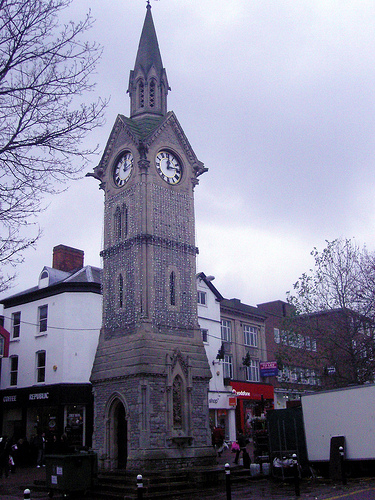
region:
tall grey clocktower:
[77, 10, 248, 468]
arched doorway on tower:
[63, 369, 146, 482]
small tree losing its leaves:
[262, 215, 373, 375]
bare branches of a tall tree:
[3, 6, 117, 265]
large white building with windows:
[11, 248, 129, 401]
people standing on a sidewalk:
[3, 424, 54, 473]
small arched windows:
[106, 195, 137, 316]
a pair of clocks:
[85, 115, 200, 200]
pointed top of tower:
[101, 0, 195, 125]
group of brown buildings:
[198, 266, 372, 451]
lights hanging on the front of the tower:
[101, 184, 202, 335]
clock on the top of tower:
[152, 143, 188, 186]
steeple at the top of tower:
[123, 4, 182, 113]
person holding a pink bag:
[229, 426, 251, 464]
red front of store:
[226, 376, 288, 443]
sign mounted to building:
[256, 357, 284, 378]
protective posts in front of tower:
[220, 462, 235, 497]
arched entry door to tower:
[99, 391, 139, 481]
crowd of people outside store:
[27, 428, 77, 467]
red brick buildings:
[257, 301, 372, 384]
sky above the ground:
[253, 69, 331, 137]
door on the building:
[90, 397, 145, 464]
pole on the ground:
[214, 461, 249, 492]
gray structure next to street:
[124, 269, 186, 368]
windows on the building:
[268, 331, 327, 352]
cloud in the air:
[237, 45, 333, 138]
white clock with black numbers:
[149, 143, 220, 189]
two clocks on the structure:
[94, 141, 199, 196]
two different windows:
[18, 309, 67, 375]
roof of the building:
[128, 119, 155, 139]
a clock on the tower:
[153, 145, 187, 187]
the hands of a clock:
[162, 152, 178, 171]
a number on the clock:
[158, 150, 166, 159]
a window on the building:
[34, 299, 53, 339]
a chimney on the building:
[48, 241, 88, 274]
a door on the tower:
[104, 394, 134, 469]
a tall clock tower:
[83, 1, 236, 470]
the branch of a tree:
[0, 104, 32, 155]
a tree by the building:
[263, 231, 373, 405]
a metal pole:
[217, 458, 242, 499]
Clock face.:
[150, 142, 192, 188]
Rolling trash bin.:
[34, 440, 108, 497]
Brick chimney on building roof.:
[43, 239, 91, 276]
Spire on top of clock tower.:
[126, 2, 175, 120]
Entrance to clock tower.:
[98, 387, 140, 479]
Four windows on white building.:
[8, 297, 56, 387]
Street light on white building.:
[196, 269, 219, 284]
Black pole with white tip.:
[279, 449, 309, 498]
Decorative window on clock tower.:
[159, 349, 199, 451]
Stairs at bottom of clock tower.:
[98, 441, 264, 496]